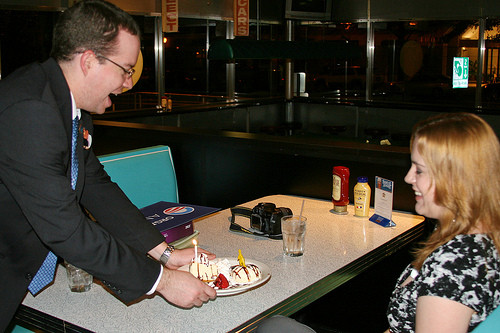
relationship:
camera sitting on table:
[228, 200, 310, 247] [138, 174, 355, 304]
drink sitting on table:
[281, 214, 308, 259] [12, 190, 427, 331]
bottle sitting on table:
[329, 166, 350, 216] [12, 190, 427, 331]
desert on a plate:
[187, 252, 265, 286] [177, 255, 277, 295]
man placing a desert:
[1, 4, 217, 331] [180, 251, 254, 287]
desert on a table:
[180, 251, 254, 287] [12, 190, 427, 331]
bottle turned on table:
[329, 166, 350, 216] [12, 190, 427, 331]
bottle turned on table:
[354, 176, 372, 217] [12, 190, 427, 331]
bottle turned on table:
[329, 166, 350, 216] [311, 212, 370, 265]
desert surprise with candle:
[180, 251, 254, 287] [237, 247, 245, 264]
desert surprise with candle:
[180, 251, 254, 287] [192, 237, 199, 264]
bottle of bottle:
[294, 169, 378, 214] [329, 166, 350, 216]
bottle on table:
[329, 166, 350, 216] [68, 196, 410, 320]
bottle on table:
[352, 176, 371, 218] [12, 190, 427, 331]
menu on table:
[367, 174, 392, 229] [12, 190, 427, 331]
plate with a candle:
[152, 242, 272, 302] [190, 236, 200, 262]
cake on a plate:
[185, 256, 225, 282] [181, 236, 275, 298]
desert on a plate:
[180, 251, 254, 287] [181, 236, 275, 298]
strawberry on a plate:
[214, 272, 231, 290] [171, 252, 293, 287]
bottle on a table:
[329, 166, 350, 216] [12, 190, 427, 331]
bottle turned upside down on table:
[329, 166, 350, 216] [12, 190, 427, 331]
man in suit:
[1, 4, 217, 331] [0, 56, 165, 331]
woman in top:
[351, 112, 486, 329] [384, 231, 481, 331]